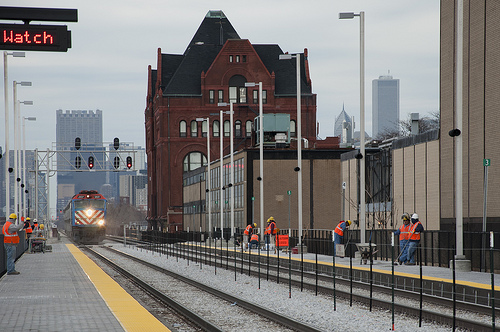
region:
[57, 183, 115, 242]
Train arriving in the station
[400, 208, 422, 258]
Worker in the train station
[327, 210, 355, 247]
Worker in the train station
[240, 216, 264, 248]
Worker in the train station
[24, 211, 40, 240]
Worker in the train station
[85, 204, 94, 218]
Light on a train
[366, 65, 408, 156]
Tall skyscraper in the distance view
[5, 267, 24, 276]
Man wearing shoes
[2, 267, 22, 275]
Man is wearing shoes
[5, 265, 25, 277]
Man wearing brown shoes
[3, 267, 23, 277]
Man is wearing brown shoes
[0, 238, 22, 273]
Man wearing pants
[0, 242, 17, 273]
Man wearing blue pants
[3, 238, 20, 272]
Man is wearing blue pants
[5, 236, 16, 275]
Man is wearing jeans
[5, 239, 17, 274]
Man is wearing blue jeans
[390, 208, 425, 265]
Men wearing orange vests.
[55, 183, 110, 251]
Train on the tracks.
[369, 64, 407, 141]
Skyscrapers in the background.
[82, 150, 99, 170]
Red signal on street light.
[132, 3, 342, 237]
Brick building beside the track.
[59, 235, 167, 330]
Yellow line on the platform.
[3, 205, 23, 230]
Yellow helmet on the man.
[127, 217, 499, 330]
Black poles between the tracks.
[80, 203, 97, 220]
Light on the train.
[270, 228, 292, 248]
Orange construction sign.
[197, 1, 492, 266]
street light fixtures on tall utility poles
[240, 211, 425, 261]
workers in orange high visibility vests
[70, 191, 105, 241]
train arriving at city train station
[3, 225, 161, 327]
ttrain station platform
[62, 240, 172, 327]
solid yellow platform warning stripe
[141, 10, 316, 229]
tall multi-story city building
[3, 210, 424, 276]
railway workers on both platforms at train station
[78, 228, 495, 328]
two sets of train tracks with barrier fencing in between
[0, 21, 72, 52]
safety sign WATCH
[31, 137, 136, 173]
train signals on horizontal support structure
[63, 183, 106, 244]
this is a train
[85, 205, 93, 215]
this is the front light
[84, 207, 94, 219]
the light is on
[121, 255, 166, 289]
these are the rails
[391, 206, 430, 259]
these are the workers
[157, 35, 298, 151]
this is a building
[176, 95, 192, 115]
the wall is brown in color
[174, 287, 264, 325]
the rails are metallic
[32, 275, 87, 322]
this is a pavement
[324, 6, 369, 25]
this is a street light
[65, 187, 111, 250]
train moving up track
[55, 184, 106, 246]
a long blue and yellow train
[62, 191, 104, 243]
a large passenger train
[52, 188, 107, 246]
a train on a track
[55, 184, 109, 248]
a train on the rails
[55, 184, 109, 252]
a travelling train on the tracks